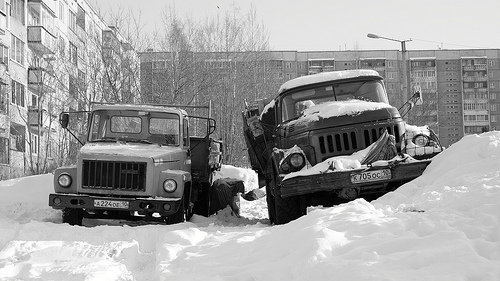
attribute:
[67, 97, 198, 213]
truck — black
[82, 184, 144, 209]
plate — license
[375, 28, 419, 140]
light — street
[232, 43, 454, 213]
truck — old, black, volvo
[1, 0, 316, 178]
trees — bare, leafless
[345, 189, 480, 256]
snow — white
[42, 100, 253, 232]
truck — old, grey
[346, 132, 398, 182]
ground — parked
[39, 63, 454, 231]
trucks — parked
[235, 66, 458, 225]
vehicle — old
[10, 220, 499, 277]
snow — white